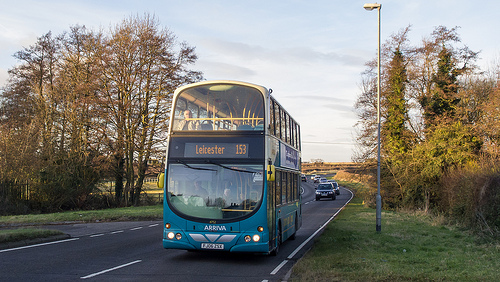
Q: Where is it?
A: This is at the road.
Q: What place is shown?
A: It is a road.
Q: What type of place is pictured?
A: It is a road.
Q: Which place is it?
A: It is a road.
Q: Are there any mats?
A: No, there are no mats.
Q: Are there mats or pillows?
A: No, there are no mats or pillows.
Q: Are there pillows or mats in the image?
A: No, there are no mats or pillows.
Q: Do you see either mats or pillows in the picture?
A: No, there are no mats or pillows.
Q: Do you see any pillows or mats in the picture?
A: No, there are no mats or pillows.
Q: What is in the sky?
A: The clouds are in the sky.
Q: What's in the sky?
A: The clouds are in the sky.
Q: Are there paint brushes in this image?
A: No, there are no paint brushes.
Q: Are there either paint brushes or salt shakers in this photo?
A: No, there are no paint brushes or salt shakers.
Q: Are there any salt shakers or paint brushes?
A: No, there are no paint brushes or salt shakers.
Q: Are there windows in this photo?
A: Yes, there is a window.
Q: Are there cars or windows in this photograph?
A: Yes, there is a window.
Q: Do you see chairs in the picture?
A: No, there are no chairs.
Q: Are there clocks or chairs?
A: No, there are no chairs or clocks.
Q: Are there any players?
A: No, there are no players.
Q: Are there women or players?
A: No, there are no players or women.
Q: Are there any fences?
A: No, there are no fences.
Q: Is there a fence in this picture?
A: No, there are no fences.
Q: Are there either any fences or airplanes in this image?
A: No, there are no fences or airplanes.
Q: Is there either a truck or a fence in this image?
A: No, there are no fences or trucks.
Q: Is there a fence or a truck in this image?
A: No, there are no fences or trucks.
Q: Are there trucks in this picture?
A: No, there are no trucks.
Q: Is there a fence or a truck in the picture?
A: No, there are no trucks or fences.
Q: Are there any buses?
A: Yes, there is a bus.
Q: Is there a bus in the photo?
A: Yes, there is a bus.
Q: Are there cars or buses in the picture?
A: Yes, there is a bus.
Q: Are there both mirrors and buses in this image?
A: Yes, there are both a bus and a mirror.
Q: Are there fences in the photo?
A: No, there are no fences.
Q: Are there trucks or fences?
A: No, there are no fences or trucks.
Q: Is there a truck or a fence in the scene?
A: No, there are no fences or trucks.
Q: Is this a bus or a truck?
A: This is a bus.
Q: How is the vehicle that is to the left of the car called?
A: The vehicle is a bus.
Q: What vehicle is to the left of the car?
A: The vehicle is a bus.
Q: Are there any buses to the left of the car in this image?
A: Yes, there is a bus to the left of the car.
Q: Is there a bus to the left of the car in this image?
A: Yes, there is a bus to the left of the car.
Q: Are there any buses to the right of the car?
A: No, the bus is to the left of the car.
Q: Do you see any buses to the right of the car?
A: No, the bus is to the left of the car.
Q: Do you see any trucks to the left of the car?
A: No, there is a bus to the left of the car.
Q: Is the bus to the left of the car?
A: Yes, the bus is to the left of the car.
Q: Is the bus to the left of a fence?
A: No, the bus is to the left of the car.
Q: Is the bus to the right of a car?
A: No, the bus is to the left of a car.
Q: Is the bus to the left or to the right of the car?
A: The bus is to the left of the car.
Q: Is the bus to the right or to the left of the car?
A: The bus is to the left of the car.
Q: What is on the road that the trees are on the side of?
A: The bus is on the road.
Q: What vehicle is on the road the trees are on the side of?
A: The vehicle is a bus.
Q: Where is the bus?
A: The bus is on the road.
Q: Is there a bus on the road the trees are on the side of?
A: Yes, there is a bus on the road.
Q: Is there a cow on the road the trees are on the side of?
A: No, there is a bus on the road.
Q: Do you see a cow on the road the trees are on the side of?
A: No, there is a bus on the road.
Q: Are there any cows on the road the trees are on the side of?
A: No, there is a bus on the road.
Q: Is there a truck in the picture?
A: No, there are no trucks.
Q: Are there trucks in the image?
A: No, there are no trucks.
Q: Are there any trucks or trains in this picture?
A: No, there are no trucks or trains.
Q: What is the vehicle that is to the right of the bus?
A: The vehicle is a car.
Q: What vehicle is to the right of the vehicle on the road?
A: The vehicle is a car.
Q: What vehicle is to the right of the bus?
A: The vehicle is a car.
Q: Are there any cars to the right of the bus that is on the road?
A: Yes, there is a car to the right of the bus.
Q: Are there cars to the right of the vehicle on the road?
A: Yes, there is a car to the right of the bus.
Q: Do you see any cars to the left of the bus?
A: No, the car is to the right of the bus.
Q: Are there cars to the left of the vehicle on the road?
A: No, the car is to the right of the bus.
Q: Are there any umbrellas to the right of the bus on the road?
A: No, there is a car to the right of the bus.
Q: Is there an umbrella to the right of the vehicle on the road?
A: No, there is a car to the right of the bus.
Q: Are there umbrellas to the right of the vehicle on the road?
A: No, there is a car to the right of the bus.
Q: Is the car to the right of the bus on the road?
A: Yes, the car is to the right of the bus.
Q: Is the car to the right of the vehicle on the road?
A: Yes, the car is to the right of the bus.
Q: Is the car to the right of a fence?
A: No, the car is to the right of the bus.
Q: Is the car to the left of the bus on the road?
A: No, the car is to the right of the bus.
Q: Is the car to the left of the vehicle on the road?
A: No, the car is to the right of the bus.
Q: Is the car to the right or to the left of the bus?
A: The car is to the right of the bus.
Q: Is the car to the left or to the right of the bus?
A: The car is to the right of the bus.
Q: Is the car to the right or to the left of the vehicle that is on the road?
A: The car is to the right of the bus.